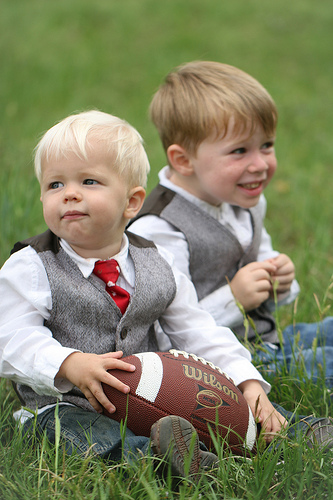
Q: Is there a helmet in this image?
A: No, there are no helmets.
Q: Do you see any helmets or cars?
A: No, there are no helmets or cars.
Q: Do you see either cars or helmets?
A: No, there are no helmets or cars.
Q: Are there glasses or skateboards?
A: No, there are no glasses or skateboards.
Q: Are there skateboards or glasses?
A: No, there are no glasses or skateboards.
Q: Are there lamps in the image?
A: No, there are no lamps.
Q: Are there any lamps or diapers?
A: No, there are no lamps or diapers.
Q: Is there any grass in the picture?
A: Yes, there is grass.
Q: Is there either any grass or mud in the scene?
A: Yes, there is grass.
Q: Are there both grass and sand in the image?
A: No, there is grass but no sand.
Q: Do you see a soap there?
A: No, there are no soaps.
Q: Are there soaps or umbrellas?
A: No, there are no soaps or umbrellas.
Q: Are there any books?
A: No, there are no books.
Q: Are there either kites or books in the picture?
A: No, there are no books or kites.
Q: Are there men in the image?
A: No, there are no men.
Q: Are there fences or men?
A: No, there are no men or fences.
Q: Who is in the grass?
A: The boy is in the grass.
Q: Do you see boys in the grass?
A: Yes, there is a boy in the grass.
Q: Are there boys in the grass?
A: Yes, there is a boy in the grass.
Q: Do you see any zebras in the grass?
A: No, there is a boy in the grass.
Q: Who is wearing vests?
A: The boy is wearing vests.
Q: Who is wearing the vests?
A: The boy is wearing vests.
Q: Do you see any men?
A: No, there are no men.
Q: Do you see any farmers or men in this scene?
A: No, there are no men or farmers.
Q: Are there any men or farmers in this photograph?
A: No, there are no men or farmers.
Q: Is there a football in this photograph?
A: Yes, there is a football.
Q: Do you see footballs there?
A: Yes, there is a football.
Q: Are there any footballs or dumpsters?
A: Yes, there is a football.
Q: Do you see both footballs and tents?
A: No, there is a football but no tents.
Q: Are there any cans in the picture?
A: No, there are no cans.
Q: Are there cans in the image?
A: No, there are no cans.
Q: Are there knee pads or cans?
A: No, there are no cans or knee pads.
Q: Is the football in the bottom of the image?
A: Yes, the football is in the bottom of the image.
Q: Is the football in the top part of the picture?
A: No, the football is in the bottom of the image.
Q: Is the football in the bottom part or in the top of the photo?
A: The football is in the bottom of the image.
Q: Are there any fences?
A: No, there are no fences.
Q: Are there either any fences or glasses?
A: No, there are no fences or glasses.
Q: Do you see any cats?
A: No, there are no cats.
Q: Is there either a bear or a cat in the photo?
A: No, there are no cats or bears.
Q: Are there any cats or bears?
A: No, there are no cats or bears.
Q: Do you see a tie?
A: Yes, there is a tie.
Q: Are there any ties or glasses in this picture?
A: Yes, there is a tie.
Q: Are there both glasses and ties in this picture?
A: No, there is a tie but no glasses.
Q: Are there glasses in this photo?
A: No, there are no glasses.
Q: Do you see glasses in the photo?
A: No, there are no glasses.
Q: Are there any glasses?
A: No, there are no glasses.